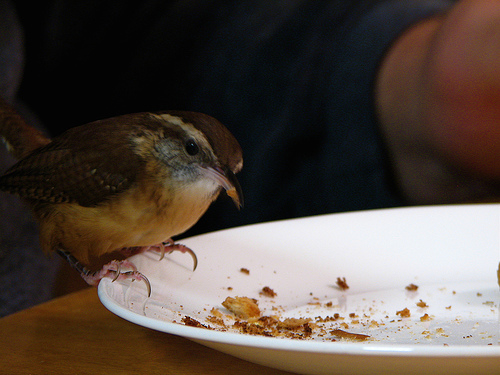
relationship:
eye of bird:
[182, 138, 199, 156] [5, 106, 245, 294]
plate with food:
[93, 203, 500, 374] [180, 294, 369, 337]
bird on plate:
[0, 106, 245, 316] [93, 203, 500, 374]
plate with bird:
[93, 203, 500, 374] [5, 106, 245, 294]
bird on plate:
[5, 106, 245, 294] [93, 203, 500, 374]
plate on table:
[93, 203, 500, 374] [1, 280, 302, 373]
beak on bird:
[103, 112, 258, 222] [5, 106, 245, 294]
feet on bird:
[68, 236, 198, 296] [5, 106, 245, 294]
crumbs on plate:
[183, 266, 440, 340] [89, 183, 481, 335]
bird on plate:
[0, 106, 245, 316] [154, 204, 475, 358]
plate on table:
[80, 107, 467, 374] [1, 274, 476, 366]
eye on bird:
[182, 138, 199, 156] [5, 106, 245, 294]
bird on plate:
[0, 106, 245, 316] [192, 231, 430, 372]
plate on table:
[93, 203, 500, 374] [5, 267, 285, 365]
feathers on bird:
[119, 116, 188, 171] [5, 106, 245, 294]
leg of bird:
[56, 242, 154, 301] [15, 92, 204, 287]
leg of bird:
[133, 234, 203, 274] [30, 60, 290, 308]